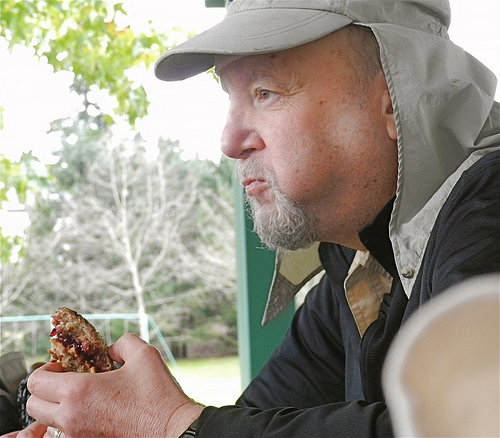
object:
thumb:
[104, 332, 158, 369]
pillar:
[236, 195, 293, 389]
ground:
[421, 151, 465, 194]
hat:
[149, 0, 500, 327]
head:
[200, 0, 470, 253]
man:
[1, 0, 495, 438]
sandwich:
[47, 302, 118, 373]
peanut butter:
[54, 311, 100, 372]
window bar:
[220, 0, 299, 409]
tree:
[0, 113, 238, 353]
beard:
[235, 183, 323, 257]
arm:
[229, 267, 355, 415]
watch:
[175, 406, 206, 436]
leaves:
[0, 0, 180, 127]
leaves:
[31, 0, 121, 90]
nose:
[216, 99, 263, 163]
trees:
[0, 0, 173, 275]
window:
[1, 0, 239, 407]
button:
[400, 266, 414, 278]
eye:
[253, 86, 284, 104]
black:
[295, 332, 322, 350]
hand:
[21, 329, 205, 435]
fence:
[0, 316, 53, 356]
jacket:
[190, 149, 498, 436]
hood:
[153, 0, 498, 324]